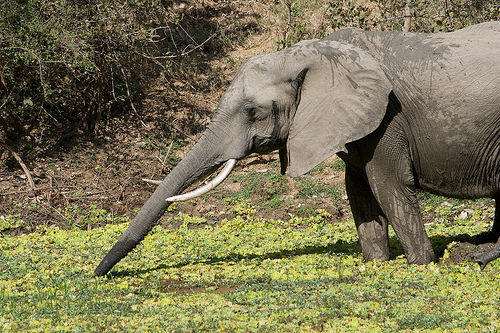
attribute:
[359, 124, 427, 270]
leg — wet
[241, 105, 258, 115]
eye — dark, open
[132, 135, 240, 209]
tusks — white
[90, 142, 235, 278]
trunk — gray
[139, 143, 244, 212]
tusks — ivory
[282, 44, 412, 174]
ear — grey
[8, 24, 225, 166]
bush — green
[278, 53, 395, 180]
ear — large, grey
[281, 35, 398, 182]
gray ear — floppy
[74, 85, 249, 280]
elephant trunk — long, grey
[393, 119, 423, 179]
texture — wrinkled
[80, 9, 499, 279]
elephant — wet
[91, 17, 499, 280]
large elephant — old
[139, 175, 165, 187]
tusk — sharp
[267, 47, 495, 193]
elephant — old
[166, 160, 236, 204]
tusk — white, large